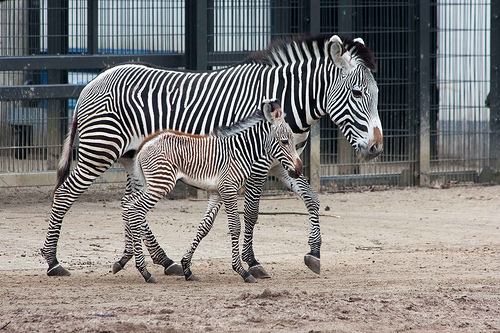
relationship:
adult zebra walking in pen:
[38, 28, 388, 275] [4, 7, 498, 328]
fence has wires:
[2, 1, 499, 200] [445, 51, 464, 112]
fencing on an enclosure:
[438, 4, 490, 181] [22, 50, 498, 292]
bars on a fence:
[0, 45, 270, 105] [2, 1, 499, 200]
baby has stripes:
[113, 99, 300, 285] [234, 132, 264, 173]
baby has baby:
[113, 99, 300, 285] [113, 99, 300, 285]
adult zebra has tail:
[38, 28, 388, 275] [48, 101, 78, 193]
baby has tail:
[113, 99, 300, 285] [131, 157, 143, 190]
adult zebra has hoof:
[38, 28, 388, 275] [299, 250, 326, 278]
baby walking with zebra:
[113, 99, 300, 285] [46, 33, 451, 283]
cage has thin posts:
[3, 1, 498, 186] [417, 2, 429, 187]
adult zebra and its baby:
[38, 28, 388, 275] [114, 96, 301, 278]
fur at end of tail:
[55, 130, 75, 188] [45, 108, 80, 196]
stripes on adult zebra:
[122, 75, 144, 134] [38, 28, 388, 275]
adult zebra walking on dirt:
[38, 28, 388, 275] [0, 182, 500, 331]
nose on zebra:
[290, 157, 301, 177] [111, 98, 302, 283]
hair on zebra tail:
[50, 128, 75, 204] [53, 96, 78, 199]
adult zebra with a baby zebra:
[38, 28, 388, 275] [121, 94, 307, 276]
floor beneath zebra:
[0, 163, 499, 330] [78, 44, 363, 247]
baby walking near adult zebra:
[113, 99, 300, 285] [38, 28, 388, 275]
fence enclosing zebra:
[2, 1, 499, 200] [108, 90, 309, 287]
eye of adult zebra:
[347, 78, 368, 106] [77, 28, 387, 272]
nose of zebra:
[357, 122, 388, 149] [55, 38, 390, 272]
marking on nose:
[372, 121, 386, 143] [357, 122, 388, 149]